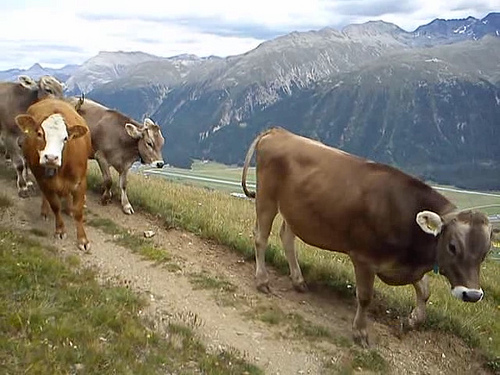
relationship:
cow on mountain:
[242, 127, 478, 331] [2, 2, 497, 192]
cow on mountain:
[18, 95, 95, 257] [2, 2, 497, 192]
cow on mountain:
[66, 95, 168, 215] [2, 2, 497, 192]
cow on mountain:
[0, 73, 67, 196] [2, 2, 497, 192]